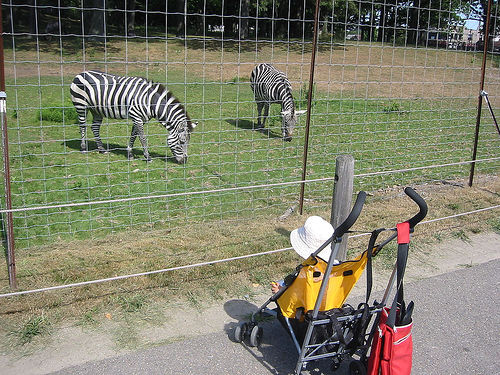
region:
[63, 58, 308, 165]
zebras in a pen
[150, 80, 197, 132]
mane on a zebra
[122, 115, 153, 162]
front legs of zebra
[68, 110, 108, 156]
back legs of zebra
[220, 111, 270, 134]
shadow on green grass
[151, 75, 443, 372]
a stroller in front a pen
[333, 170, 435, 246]
handles of stroller are black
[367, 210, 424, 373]
a red bag hangs from handle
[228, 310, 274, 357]
a wheel in front of stroller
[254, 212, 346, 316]
a white hat of baby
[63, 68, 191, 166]
Zebra eating grass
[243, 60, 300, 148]
Zebra eating grass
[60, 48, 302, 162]
Two zebras eating grass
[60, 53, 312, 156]
Two zebras behind a fence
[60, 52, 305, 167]
Two zebras behind a fence eating grass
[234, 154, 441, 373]
Child in stroller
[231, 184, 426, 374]
Child wearing white hat in stroller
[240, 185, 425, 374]
Child in yellow stroller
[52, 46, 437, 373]
Child in stroller watching two zebras eating grass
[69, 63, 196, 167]
a black and white zebra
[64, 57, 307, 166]
two zebras grazing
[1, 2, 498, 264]
two zebras behind a fence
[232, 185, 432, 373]
a yellow stroller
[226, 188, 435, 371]
yellow stroller with a child inside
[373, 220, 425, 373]
red bag hanging on a handle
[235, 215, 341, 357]
child watching the zebras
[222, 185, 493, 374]
yellow stroller on the walkway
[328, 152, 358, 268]
wooden post on the ground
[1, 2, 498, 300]
zebras enclose in a fenced display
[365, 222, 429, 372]
Red bag on stroller.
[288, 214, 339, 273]
White hat on child.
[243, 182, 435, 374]
Stroller in the forefront.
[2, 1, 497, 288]
Wire fence in front of stroller.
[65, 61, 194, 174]
Zebra eating grass.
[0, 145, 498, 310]
Double line rope in front of fence.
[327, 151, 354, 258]
Wood fence pole for rope.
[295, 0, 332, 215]
Metal fence post.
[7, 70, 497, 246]
Green grass covering the ground.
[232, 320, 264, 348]
Black wheels on the stroller.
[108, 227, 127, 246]
edge of a net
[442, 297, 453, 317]
part of a road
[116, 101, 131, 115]
part of a zebra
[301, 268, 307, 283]
part of a ride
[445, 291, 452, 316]
part of a road